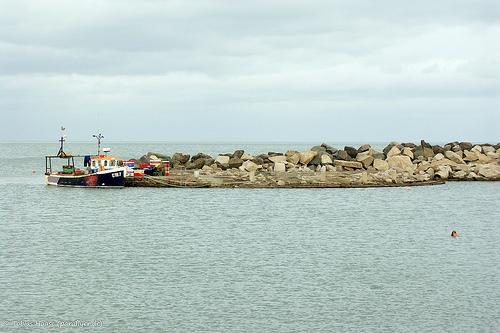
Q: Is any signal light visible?
A: No, there are no traffic lights.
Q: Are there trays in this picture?
A: No, there are no trays.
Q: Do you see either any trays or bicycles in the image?
A: No, there are no trays or bicycles.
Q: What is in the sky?
A: The clouds are in the sky.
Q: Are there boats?
A: Yes, there is a boat.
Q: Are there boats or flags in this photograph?
A: Yes, there is a boat.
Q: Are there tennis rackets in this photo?
A: No, there are no tennis rackets.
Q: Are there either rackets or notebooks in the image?
A: No, there are no rackets or notebooks.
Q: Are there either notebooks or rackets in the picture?
A: No, there are no rackets or notebooks.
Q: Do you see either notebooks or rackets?
A: No, there are no rackets or notebooks.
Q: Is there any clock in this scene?
A: No, there are no clocks.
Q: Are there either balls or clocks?
A: No, there are no clocks or balls.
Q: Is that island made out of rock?
A: Yes, the island is made of rock.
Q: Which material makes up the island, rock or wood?
A: The island is made of rock.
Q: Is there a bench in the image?
A: No, there are no benches.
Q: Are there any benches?
A: No, there are no benches.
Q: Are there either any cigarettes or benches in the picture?
A: No, there are no benches or cigarettes.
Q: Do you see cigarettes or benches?
A: No, there are no benches or cigarettes.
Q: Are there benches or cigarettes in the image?
A: No, there are no benches or cigarettes.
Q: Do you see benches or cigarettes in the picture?
A: No, there are no benches or cigarettes.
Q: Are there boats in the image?
A: Yes, there is a boat.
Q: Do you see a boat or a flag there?
A: Yes, there is a boat.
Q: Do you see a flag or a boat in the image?
A: Yes, there is a boat.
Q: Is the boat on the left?
A: Yes, the boat is on the left of the image.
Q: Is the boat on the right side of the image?
A: No, the boat is on the left of the image.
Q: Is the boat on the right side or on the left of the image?
A: The boat is on the left of the image.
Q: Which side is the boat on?
A: The boat is on the left of the image.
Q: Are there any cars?
A: No, there are no cars.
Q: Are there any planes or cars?
A: No, there are no cars or planes.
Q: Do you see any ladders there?
A: No, there are no ladders.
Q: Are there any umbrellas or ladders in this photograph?
A: No, there are no ladders or umbrellas.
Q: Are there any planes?
A: No, there are no planes.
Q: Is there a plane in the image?
A: No, there are no airplanes.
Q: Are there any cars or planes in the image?
A: No, there are no planes or cars.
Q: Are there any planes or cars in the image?
A: No, there are no planes or cars.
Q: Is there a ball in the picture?
A: No, there are no balls.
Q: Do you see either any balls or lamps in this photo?
A: No, there are no balls or lamps.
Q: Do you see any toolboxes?
A: No, there are no toolboxes.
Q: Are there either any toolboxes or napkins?
A: No, there are no toolboxes or napkins.